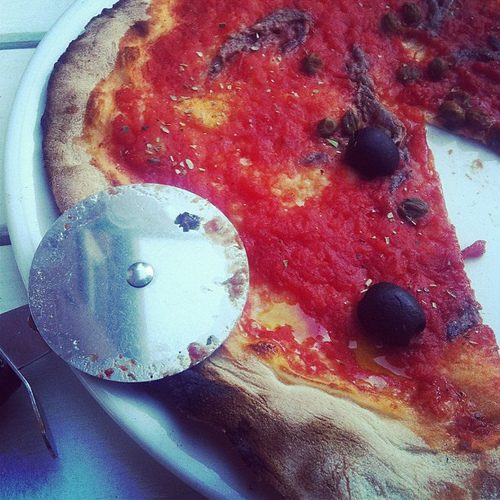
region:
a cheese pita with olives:
[60, 1, 485, 492]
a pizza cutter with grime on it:
[2, 180, 259, 487]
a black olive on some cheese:
[334, 270, 446, 371]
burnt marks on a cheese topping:
[218, 0, 428, 200]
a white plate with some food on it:
[0, 7, 494, 497]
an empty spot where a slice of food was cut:
[405, 108, 497, 336]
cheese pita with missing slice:
[30, 4, 492, 498]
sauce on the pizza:
[308, 215, 347, 255]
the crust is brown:
[273, 393, 328, 455]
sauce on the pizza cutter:
[181, 340, 210, 365]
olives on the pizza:
[348, 130, 402, 176]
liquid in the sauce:
[351, 349, 397, 381]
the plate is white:
[18, 139, 34, 184]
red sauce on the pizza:
[318, 245, 370, 280]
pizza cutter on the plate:
[8, 193, 241, 431]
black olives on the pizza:
[350, 110, 424, 335]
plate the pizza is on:
[6, 4, 488, 498]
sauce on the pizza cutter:
[33, 187, 246, 379]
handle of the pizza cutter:
[3, 309, 55, 450]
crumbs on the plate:
[439, 131, 494, 271]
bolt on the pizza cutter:
[126, 265, 151, 285]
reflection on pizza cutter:
[74, 209, 212, 349]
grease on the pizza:
[348, 327, 393, 381]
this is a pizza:
[56, 7, 497, 497]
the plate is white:
[11, 25, 476, 478]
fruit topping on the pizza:
[354, 269, 437, 356]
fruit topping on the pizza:
[346, 121, 407, 189]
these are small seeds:
[156, 136, 211, 193]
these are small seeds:
[411, 279, 463, 329]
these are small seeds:
[384, 194, 445, 268]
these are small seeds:
[156, 109, 174, 159]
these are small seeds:
[157, 151, 232, 199]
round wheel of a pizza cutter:
[28, 177, 250, 387]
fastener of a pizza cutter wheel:
[123, 260, 156, 291]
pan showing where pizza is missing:
[418, 111, 498, 363]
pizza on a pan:
[40, 1, 497, 498]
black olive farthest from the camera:
[340, 122, 403, 182]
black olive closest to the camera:
[353, 275, 425, 346]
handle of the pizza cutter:
[1, 297, 68, 463]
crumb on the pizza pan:
[462, 235, 484, 262]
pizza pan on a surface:
[3, 2, 498, 499]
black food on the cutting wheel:
[171, 213, 202, 230]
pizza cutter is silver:
[29, 160, 249, 419]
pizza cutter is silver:
[26, 163, 256, 399]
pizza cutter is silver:
[14, 169, 256, 410]